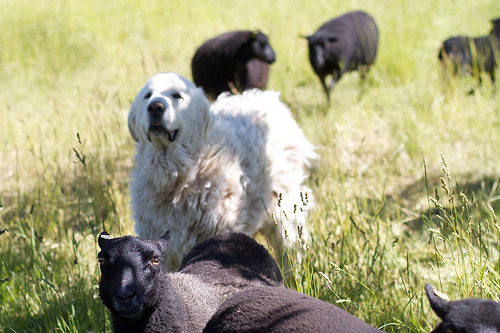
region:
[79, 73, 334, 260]
a white furry dog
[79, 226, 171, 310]
a black sheep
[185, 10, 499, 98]
three sheep in a field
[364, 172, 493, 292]
tall green grass in a field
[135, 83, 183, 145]
black nose on a dog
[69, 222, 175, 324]
black ears on a sheep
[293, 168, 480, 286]
tall green grass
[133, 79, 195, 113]
a dog's black eyes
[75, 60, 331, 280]
a large white dog standing in a field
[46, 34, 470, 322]
a dog hearding sheep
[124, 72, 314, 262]
White dog with fluffy hair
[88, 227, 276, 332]
Black sheep with brown eyes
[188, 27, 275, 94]
Blurry black sheep with head turned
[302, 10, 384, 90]
Blurry black sheep walking forward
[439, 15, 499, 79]
Blurry black sheep laying down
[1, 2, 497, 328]
Dog and sheep against glass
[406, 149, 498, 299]
Tall blades of glass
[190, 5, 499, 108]
Sheep standing together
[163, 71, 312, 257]
Dog hair blowing in the wind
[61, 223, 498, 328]
Sheep grazing in the grass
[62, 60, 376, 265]
A white dog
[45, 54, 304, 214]
A white dog with a black nose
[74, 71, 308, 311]
A white dog and black sheep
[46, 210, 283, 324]
A black sheep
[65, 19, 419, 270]
animals standing in green grass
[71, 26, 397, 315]
animals standing in tall grass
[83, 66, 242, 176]
the head of a dog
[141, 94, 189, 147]
the nose of a dog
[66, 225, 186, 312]
the head of a sheep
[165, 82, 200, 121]
the eye of a dog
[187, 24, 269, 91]
a round fluffy black sheep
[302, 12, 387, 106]
a round fluffy black sheep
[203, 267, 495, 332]
a round fluffy black sheep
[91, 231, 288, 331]
a round fluffy black sheep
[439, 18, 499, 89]
a round fluffy black sheep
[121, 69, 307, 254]
a round fluffy white dog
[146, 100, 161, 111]
the black nose of a dog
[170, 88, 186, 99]
the black eye of a dog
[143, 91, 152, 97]
the black eye of a dog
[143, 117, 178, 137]
the black mouth of a dog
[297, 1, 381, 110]
black sheep is standing next to a black sheep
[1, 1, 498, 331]
black sheep in a grassy field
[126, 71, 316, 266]
white woolly dog in field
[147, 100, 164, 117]
black nose on dog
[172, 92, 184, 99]
black eyes on dog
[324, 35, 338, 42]
ear on black sheep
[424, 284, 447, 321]
ear is sticking up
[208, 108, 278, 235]
shadow on dogs' back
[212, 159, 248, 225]
parch of light on dog's back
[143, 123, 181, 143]
white dog's mouth